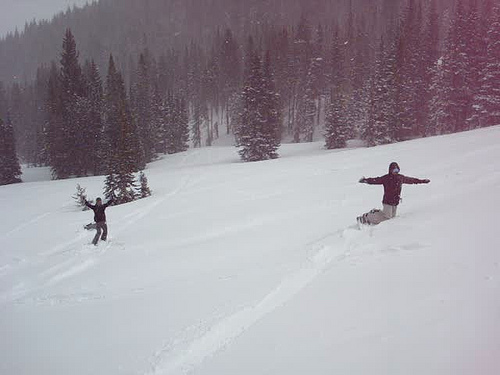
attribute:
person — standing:
[358, 162, 428, 224]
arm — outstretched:
[357, 173, 386, 184]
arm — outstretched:
[402, 175, 431, 185]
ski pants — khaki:
[362, 198, 400, 227]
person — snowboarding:
[355, 133, 425, 279]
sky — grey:
[5, 7, 93, 34]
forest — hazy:
[67, 52, 273, 138]